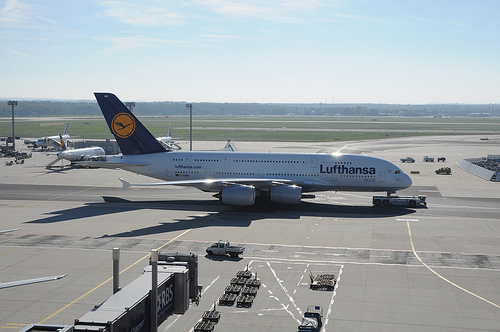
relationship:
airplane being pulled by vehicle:
[58, 82, 418, 228] [371, 188, 430, 212]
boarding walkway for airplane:
[67, 246, 210, 329] [58, 82, 418, 228]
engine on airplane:
[212, 185, 260, 207] [48, 81, 414, 208]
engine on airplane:
[270, 185, 303, 206] [58, 82, 418, 228]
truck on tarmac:
[206, 239, 247, 258] [0, 209, 498, 330]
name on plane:
[316, 153, 381, 183] [48, 91, 418, 209]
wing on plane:
[103, 179, 293, 193] [84, 90, 421, 219]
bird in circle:
[117, 121, 134, 130] [108, 114, 138, 138]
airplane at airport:
[68, 93, 414, 209] [78, 104, 418, 298]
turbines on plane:
[202, 169, 298, 213] [48, 91, 418, 209]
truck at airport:
[206, 239, 247, 258] [40, 103, 408, 286]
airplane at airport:
[68, 93, 414, 209] [39, 68, 460, 295]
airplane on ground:
[68, 93, 414, 209] [320, 231, 417, 291]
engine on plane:
[270, 185, 303, 206] [24, 73, 429, 213]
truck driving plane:
[201, 234, 247, 252] [58, 89, 437, 202]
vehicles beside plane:
[399, 151, 453, 184] [48, 91, 418, 209]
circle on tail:
[104, 110, 143, 137] [80, 71, 158, 174]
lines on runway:
[68, 216, 228, 246] [57, 147, 371, 280]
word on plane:
[318, 161, 378, 176] [86, 86, 411, 206]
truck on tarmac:
[206, 239, 247, 258] [0, 141, 480, 330]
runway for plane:
[3, 112, 483, 123] [84, 90, 421, 219]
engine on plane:
[208, 179, 260, 210] [84, 90, 421, 219]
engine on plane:
[256, 183, 310, 209] [84, 90, 421, 219]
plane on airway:
[84, 90, 421, 219] [0, 142, 483, 330]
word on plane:
[318, 161, 378, 176] [84, 90, 421, 219]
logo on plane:
[108, 110, 137, 140] [84, 90, 421, 219]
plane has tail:
[84, 90, 421, 219] [91, 91, 167, 153]